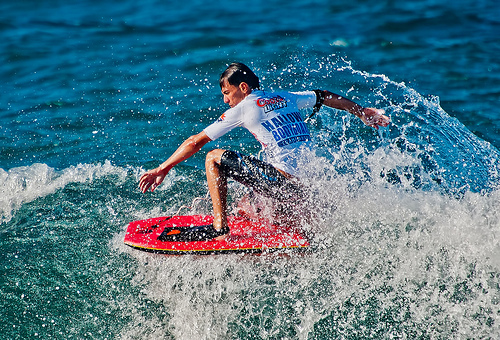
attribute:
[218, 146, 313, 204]
shorts — black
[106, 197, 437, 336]
surfboard — red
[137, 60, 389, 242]
surfer — male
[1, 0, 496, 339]
sea — blue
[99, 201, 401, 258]
surfboard — red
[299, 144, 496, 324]
water — splashed 